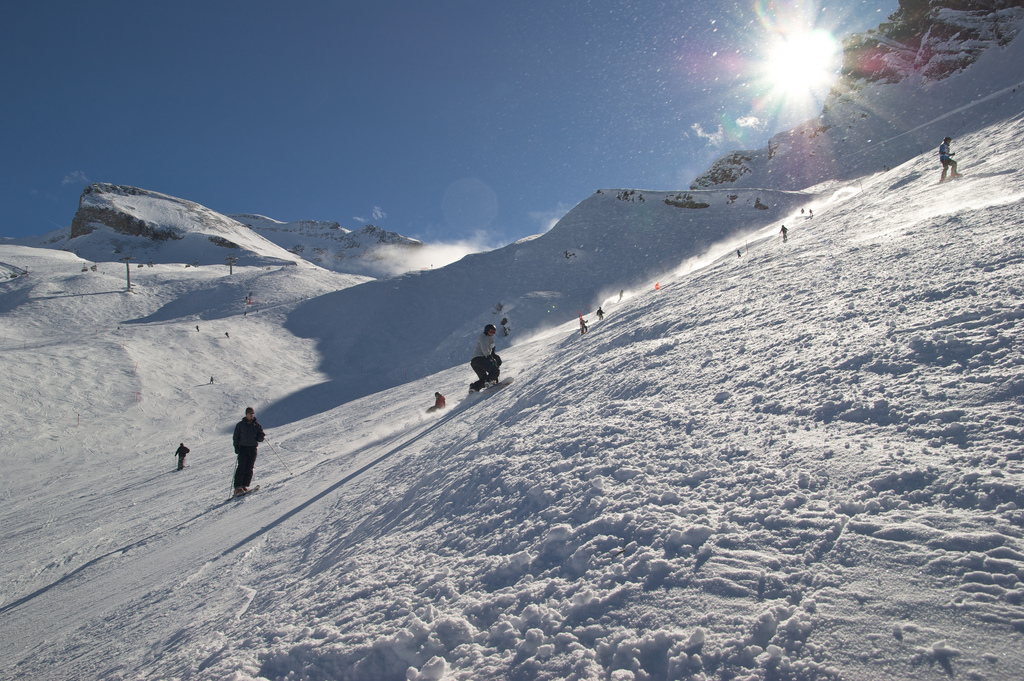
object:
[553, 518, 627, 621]
snow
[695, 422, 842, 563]
snow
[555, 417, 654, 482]
snow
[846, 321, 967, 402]
snow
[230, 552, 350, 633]
snow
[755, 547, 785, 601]
snow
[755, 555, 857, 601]
snow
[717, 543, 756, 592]
snow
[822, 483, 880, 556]
snow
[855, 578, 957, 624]
snow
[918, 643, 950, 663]
snow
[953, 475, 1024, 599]
snow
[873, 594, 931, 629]
snow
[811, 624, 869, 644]
snow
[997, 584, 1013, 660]
snow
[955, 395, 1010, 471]
snow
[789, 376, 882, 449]
snow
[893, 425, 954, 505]
snow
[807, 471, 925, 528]
snow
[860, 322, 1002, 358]
snow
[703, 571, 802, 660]
snow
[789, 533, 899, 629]
snow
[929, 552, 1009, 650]
snow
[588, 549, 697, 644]
snow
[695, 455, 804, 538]
snow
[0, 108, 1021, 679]
ground